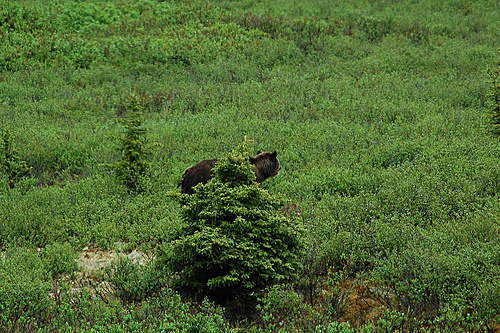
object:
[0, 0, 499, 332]
plants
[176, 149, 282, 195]
bear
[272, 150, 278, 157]
ear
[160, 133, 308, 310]
tree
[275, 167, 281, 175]
mouth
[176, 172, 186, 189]
tail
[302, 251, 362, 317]
branches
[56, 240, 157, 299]
dirt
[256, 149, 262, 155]
ears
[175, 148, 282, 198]
fur